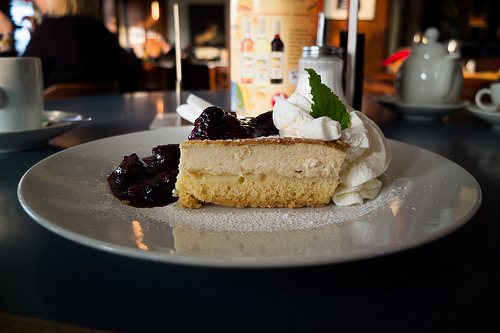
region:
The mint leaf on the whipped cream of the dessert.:
[303, 65, 355, 127]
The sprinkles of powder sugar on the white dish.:
[86, 175, 423, 228]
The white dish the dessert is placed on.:
[19, 127, 471, 263]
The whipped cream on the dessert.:
[275, 73, 394, 206]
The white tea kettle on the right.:
[399, 22, 468, 99]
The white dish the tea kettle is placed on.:
[378, 90, 466, 116]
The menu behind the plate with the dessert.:
[231, 2, 338, 134]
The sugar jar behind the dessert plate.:
[285, 45, 351, 105]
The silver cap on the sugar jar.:
[297, 36, 344, 57]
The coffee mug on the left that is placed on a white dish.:
[0, 58, 57, 126]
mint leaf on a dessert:
[308, 65, 351, 127]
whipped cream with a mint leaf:
[275, 70, 387, 202]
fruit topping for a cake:
[108, 107, 286, 207]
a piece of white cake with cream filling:
[179, 138, 343, 210]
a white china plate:
[16, 127, 481, 260]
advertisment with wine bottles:
[232, 0, 318, 118]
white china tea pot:
[376, 27, 467, 118]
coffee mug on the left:
[0, 57, 80, 144]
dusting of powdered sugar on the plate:
[113, 203, 387, 228]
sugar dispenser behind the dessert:
[297, 46, 344, 106]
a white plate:
[63, 43, 470, 267]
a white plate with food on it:
[47, 50, 435, 273]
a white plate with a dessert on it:
[33, 55, 428, 279]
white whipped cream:
[271, 56, 407, 219]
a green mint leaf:
[283, 42, 367, 164]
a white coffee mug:
[0, 42, 82, 139]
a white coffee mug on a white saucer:
[1, 50, 108, 149]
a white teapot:
[375, 15, 497, 169]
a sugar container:
[273, 25, 378, 135]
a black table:
[28, 48, 498, 329]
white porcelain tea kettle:
[377, 23, 469, 121]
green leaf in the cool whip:
[298, 63, 365, 139]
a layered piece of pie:
[157, 125, 357, 210]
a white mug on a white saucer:
[1, 41, 96, 148]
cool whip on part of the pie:
[270, 69, 404, 231]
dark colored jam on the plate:
[98, 134, 205, 215]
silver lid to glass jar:
[291, 33, 358, 64]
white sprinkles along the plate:
[152, 199, 406, 244]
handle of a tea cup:
[470, 78, 499, 118]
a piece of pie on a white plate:
[17, 96, 489, 282]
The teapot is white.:
[373, 12, 473, 123]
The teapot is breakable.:
[371, 11, 473, 132]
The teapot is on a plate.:
[369, 22, 466, 124]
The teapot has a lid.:
[371, 13, 476, 125]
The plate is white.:
[14, 110, 490, 273]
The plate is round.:
[2, 112, 488, 268]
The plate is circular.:
[15, 97, 499, 281]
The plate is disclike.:
[6, 105, 497, 286]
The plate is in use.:
[9, 93, 494, 276]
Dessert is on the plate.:
[12, 50, 489, 277]